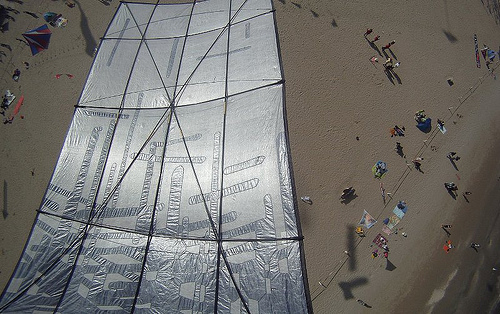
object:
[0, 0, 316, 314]
kite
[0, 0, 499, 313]
beach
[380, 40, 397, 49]
peopel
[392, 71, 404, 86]
shadows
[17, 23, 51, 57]
tent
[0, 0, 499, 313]
sand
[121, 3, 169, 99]
lines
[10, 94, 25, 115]
blanket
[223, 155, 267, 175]
pole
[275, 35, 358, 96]
air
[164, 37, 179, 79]
design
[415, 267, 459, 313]
wave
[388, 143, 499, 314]
shore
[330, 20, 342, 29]
rut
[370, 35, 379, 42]
person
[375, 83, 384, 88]
footprints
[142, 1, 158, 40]
strut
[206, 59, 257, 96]
poster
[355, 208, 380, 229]
sign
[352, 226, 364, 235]
towel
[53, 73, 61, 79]
object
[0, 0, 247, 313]
ropes